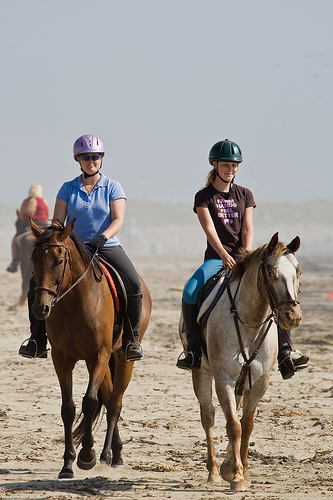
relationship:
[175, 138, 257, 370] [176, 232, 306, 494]
people riding horse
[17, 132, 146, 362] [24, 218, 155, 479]
person riding horse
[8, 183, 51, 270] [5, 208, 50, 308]
person riding horse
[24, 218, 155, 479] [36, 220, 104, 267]
horse with mane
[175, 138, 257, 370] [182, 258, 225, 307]
people wearing pants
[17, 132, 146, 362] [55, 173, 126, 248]
woman wearing shirt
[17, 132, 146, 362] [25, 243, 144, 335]
woman wearing pants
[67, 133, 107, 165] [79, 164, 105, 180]
helmet has strap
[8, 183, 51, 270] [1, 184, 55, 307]
woman riding away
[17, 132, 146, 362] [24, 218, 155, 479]
woman riding horse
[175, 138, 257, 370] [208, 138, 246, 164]
people wearing helmet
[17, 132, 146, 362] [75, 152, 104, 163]
woman wearing sunglasses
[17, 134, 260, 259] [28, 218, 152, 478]
people riding horse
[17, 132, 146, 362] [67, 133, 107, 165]
person wearing helmet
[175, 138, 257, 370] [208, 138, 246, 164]
people wears helmet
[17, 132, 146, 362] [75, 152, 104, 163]
person wearing sunglasses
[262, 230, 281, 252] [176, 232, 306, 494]
ear on horse